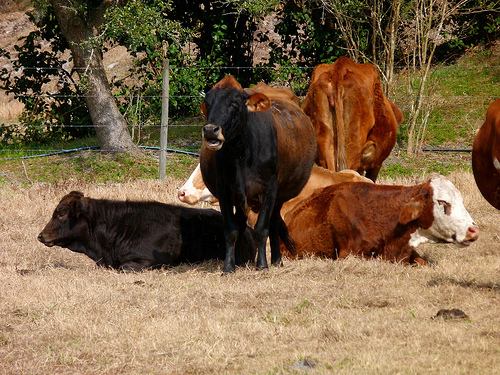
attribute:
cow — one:
[292, 175, 469, 265]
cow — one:
[197, 70, 303, 269]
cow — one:
[174, 166, 405, 210]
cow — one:
[38, 190, 242, 272]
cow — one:
[308, 57, 398, 177]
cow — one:
[460, 95, 498, 217]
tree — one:
[32, 14, 139, 155]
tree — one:
[390, 9, 456, 182]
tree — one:
[325, 2, 401, 78]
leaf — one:
[41, 92, 78, 122]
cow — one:
[43, 196, 266, 273]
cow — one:
[200, 76, 309, 266]